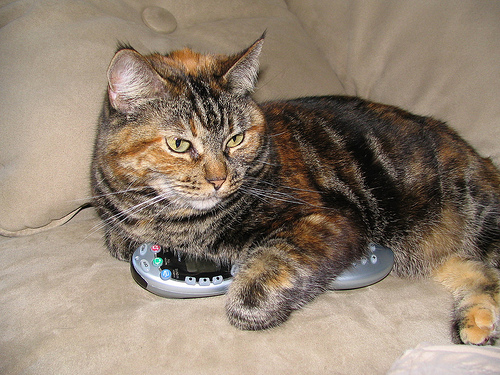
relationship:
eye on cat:
[163, 133, 193, 154] [71, 27, 498, 346]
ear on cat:
[107, 47, 168, 113] [71, 27, 498, 346]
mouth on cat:
[167, 190, 239, 212] [71, 27, 498, 346]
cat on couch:
[71, 27, 498, 346] [0, 2, 497, 372]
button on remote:
[151, 256, 165, 267] [125, 227, 399, 302]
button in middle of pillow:
[137, 5, 179, 37] [4, 3, 337, 211]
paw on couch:
[451, 295, 498, 345] [0, 2, 497, 372]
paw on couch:
[227, 274, 287, 330] [0, 2, 497, 372]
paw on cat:
[451, 295, 498, 345] [71, 27, 498, 346]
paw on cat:
[227, 274, 287, 330] [71, 27, 498, 346]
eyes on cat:
[162, 121, 249, 155] [71, 27, 498, 346]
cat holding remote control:
[71, 27, 498, 346] [135, 253, 221, 296]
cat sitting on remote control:
[71, 27, 498, 346] [135, 253, 221, 296]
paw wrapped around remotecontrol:
[227, 274, 287, 330] [125, 245, 392, 294]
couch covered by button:
[0, 2, 497, 372] [139, 8, 178, 35]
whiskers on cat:
[72, 167, 170, 227] [90, 33, 484, 333]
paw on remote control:
[227, 274, 287, 330] [129, 226, 401, 298]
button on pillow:
[119, 2, 202, 49] [2, 3, 305, 31]